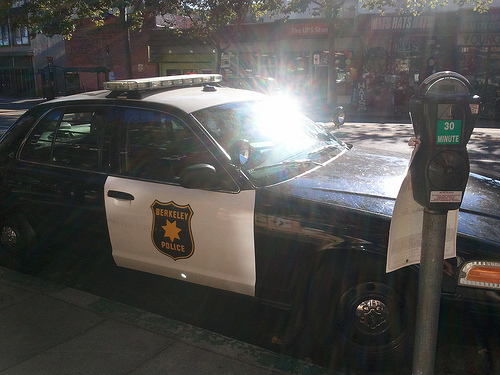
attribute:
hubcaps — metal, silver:
[352, 297, 392, 336]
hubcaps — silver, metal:
[0, 221, 18, 253]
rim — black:
[336, 281, 415, 360]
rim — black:
[0, 213, 35, 263]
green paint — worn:
[98, 298, 278, 363]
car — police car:
[5, 87, 497, 307]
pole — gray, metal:
[398, 166, 475, 373]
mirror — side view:
[177, 161, 220, 188]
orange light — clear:
[454, 258, 498, 302]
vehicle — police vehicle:
[9, 74, 498, 355]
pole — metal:
[410, 212, 447, 374]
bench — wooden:
[65, 87, 109, 95]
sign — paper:
[380, 142, 465, 274]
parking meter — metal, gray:
[415, 72, 480, 214]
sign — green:
[431, 114, 466, 154]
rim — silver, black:
[349, 292, 399, 342]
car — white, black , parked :
[9, 75, 498, 370]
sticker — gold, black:
[149, 200, 197, 258]